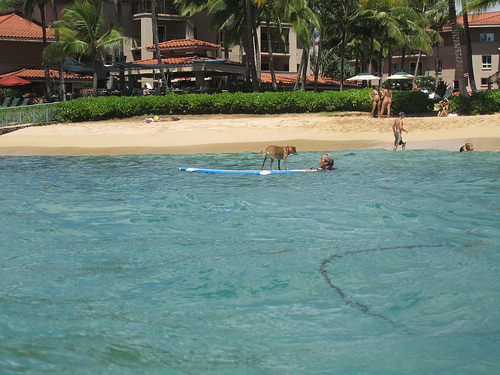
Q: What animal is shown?
A: Dog.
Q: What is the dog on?
A: Surfboard.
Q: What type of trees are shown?
A: Palm.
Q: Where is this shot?
A: Beach.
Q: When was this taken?
A: Daytime.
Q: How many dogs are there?
A: 1.